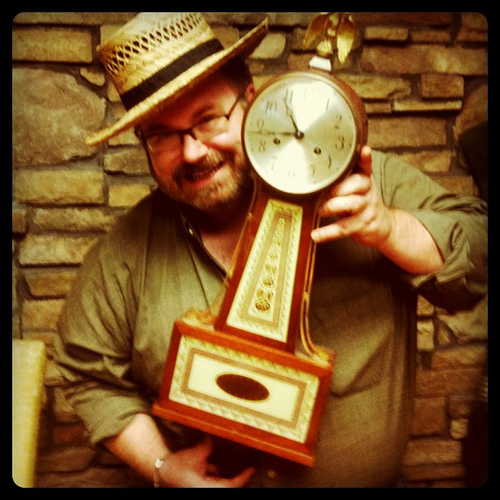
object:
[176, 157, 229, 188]
mouth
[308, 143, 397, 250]
hand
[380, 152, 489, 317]
arm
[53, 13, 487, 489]
person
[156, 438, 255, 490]
hand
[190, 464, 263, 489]
finger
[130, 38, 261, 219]
head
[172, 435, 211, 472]
finger